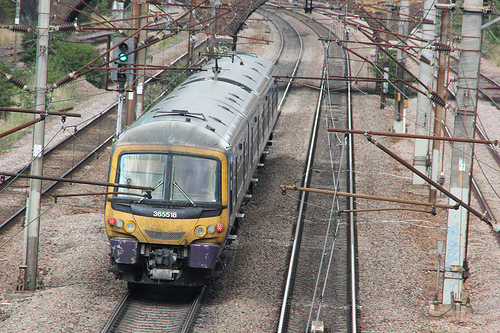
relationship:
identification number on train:
[152, 210, 179, 220] [105, 50, 281, 300]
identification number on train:
[153, 210, 177, 218] [98, 118, 225, 286]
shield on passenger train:
[113, 152, 217, 205] [102, 51, 280, 302]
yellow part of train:
[103, 140, 228, 252] [105, 50, 281, 300]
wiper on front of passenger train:
[140, 179, 162, 202] [102, 51, 280, 302]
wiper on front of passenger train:
[171, 180, 198, 205] [102, 51, 280, 302]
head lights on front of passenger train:
[192, 226, 207, 239] [102, 51, 280, 302]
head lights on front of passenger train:
[121, 220, 138, 233] [102, 51, 280, 302]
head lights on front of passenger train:
[205, 222, 216, 234] [102, 51, 280, 302]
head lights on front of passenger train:
[112, 219, 125, 229] [102, 51, 280, 302]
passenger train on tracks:
[102, 51, 280, 302] [92, 2, 363, 332]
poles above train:
[325, 123, 499, 228] [98, 74, 278, 263]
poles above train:
[3, 170, 155, 208] [98, 74, 278, 263]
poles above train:
[314, 20, 497, 113] [98, 74, 278, 263]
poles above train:
[2, 18, 201, 86] [98, 74, 278, 263]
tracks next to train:
[275, 108, 358, 325] [105, 50, 281, 300]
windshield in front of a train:
[122, 139, 237, 220] [88, 56, 310, 300]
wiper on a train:
[171, 180, 198, 205] [105, 50, 281, 300]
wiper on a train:
[140, 179, 162, 202] [105, 50, 281, 300]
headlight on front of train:
[118, 217, 137, 234] [84, 38, 297, 307]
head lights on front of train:
[116, 219, 123, 229] [84, 38, 297, 307]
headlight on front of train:
[107, 217, 116, 226] [84, 38, 297, 307]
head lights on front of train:
[194, 226, 207, 238] [84, 38, 297, 307]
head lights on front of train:
[206, 225, 215, 234] [84, 38, 297, 307]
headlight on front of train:
[213, 222, 223, 232] [84, 38, 297, 307]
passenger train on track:
[102, 51, 280, 302] [99, 283, 206, 331]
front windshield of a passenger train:
[114, 151, 218, 211] [102, 51, 280, 302]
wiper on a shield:
[171, 180, 198, 205] [170, 157, 217, 205]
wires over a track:
[0, 0, 499, 250] [261, 0, 360, 331]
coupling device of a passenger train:
[138, 242, 187, 279] [102, 51, 280, 302]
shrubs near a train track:
[45, 32, 103, 88] [233, 15, 362, 315]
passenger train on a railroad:
[102, 51, 280, 302] [107, 282, 204, 331]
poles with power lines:
[378, 2, 492, 302] [268, 12, 498, 99]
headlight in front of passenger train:
[107, 217, 116, 226] [102, 51, 280, 302]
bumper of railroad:
[107, 235, 223, 289] [106, 52, 279, 298]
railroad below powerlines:
[266, 19, 373, 329] [15, 0, 497, 88]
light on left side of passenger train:
[103, 33, 137, 87] [102, 51, 280, 302]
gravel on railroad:
[52, 254, 102, 316] [272, 19, 368, 331]